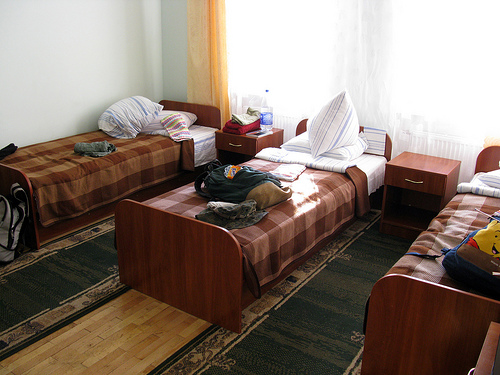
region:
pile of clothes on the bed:
[192, 150, 291, 240]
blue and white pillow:
[295, 90, 368, 157]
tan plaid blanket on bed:
[182, 142, 344, 279]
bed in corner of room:
[7, 93, 238, 229]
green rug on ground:
[2, 230, 107, 346]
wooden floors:
[66, 298, 163, 369]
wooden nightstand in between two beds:
[381, 144, 461, 239]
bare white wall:
[1, 12, 143, 113]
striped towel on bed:
[160, 110, 201, 152]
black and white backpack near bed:
[0, 192, 27, 261]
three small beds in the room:
[0, 96, 499, 373]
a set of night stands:
[215, 121, 462, 237]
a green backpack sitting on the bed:
[194, 157, 291, 206]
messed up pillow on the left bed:
[97, 94, 162, 139]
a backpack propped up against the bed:
[0, 183, 35, 257]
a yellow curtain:
[184, 0, 229, 133]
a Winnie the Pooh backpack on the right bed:
[404, 210, 497, 291]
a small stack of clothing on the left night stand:
[222, 105, 261, 135]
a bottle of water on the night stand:
[259, 87, 274, 129]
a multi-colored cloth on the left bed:
[160, 111, 192, 141]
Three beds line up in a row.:
[48, 135, 478, 345]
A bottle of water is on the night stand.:
[251, 98, 288, 132]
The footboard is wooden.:
[106, 180, 246, 322]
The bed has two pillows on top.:
[116, 81, 196, 136]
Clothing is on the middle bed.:
[208, 187, 273, 232]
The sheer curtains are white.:
[229, 15, 452, 137]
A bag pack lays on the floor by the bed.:
[1, 182, 38, 259]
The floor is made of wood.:
[65, 290, 167, 365]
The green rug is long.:
[268, 223, 374, 363]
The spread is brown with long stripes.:
[48, 128, 160, 199]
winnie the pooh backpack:
[440, 213, 498, 298]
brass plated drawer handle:
[402, 176, 424, 186]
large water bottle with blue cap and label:
[257, 87, 274, 134]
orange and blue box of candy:
[225, 164, 242, 179]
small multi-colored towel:
[157, 110, 193, 144]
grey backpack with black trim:
[0, 181, 28, 266]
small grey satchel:
[71, 139, 116, 159]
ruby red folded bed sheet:
[220, 114, 263, 137]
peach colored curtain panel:
[184, 0, 230, 132]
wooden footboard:
[113, 197, 243, 336]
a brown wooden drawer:
[379, 161, 450, 196]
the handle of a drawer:
[399, 171, 428, 191]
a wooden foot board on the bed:
[94, 189, 252, 339]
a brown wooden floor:
[1, 285, 213, 373]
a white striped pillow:
[301, 88, 363, 162]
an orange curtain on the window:
[183, 0, 233, 130]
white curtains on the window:
[222, 0, 498, 167]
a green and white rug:
[148, 209, 438, 374]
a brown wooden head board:
[293, 114, 398, 162]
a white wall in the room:
[0, 0, 157, 153]